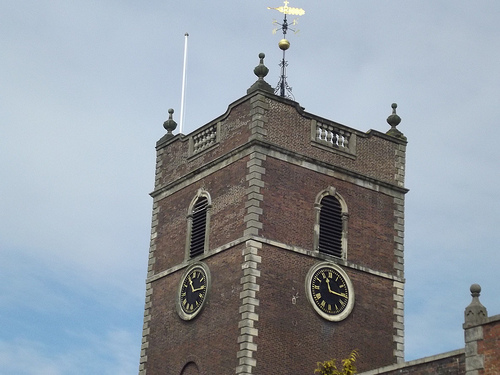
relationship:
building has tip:
[134, 51, 410, 375] [271, 33, 316, 82]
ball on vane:
[271, 35, 301, 57] [266, 13, 353, 112]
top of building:
[213, 83, 353, 124] [134, 51, 410, 375]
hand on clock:
[175, 256, 207, 308] [302, 260, 361, 325]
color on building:
[210, 132, 303, 199] [134, 112, 396, 368]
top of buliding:
[213, 83, 353, 124] [145, 112, 406, 331]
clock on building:
[302, 260, 361, 325] [134, 51, 410, 375]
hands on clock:
[183, 263, 211, 289] [302, 260, 361, 325]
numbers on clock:
[306, 271, 345, 309] [302, 260, 361, 325]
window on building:
[301, 185, 362, 239] [134, 51, 410, 375]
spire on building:
[378, 105, 412, 139] [134, 51, 410, 375]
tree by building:
[301, 341, 352, 373] [134, 112, 396, 368]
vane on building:
[266, 13, 353, 112] [134, 51, 410, 375]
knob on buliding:
[453, 278, 500, 304] [145, 112, 406, 331]